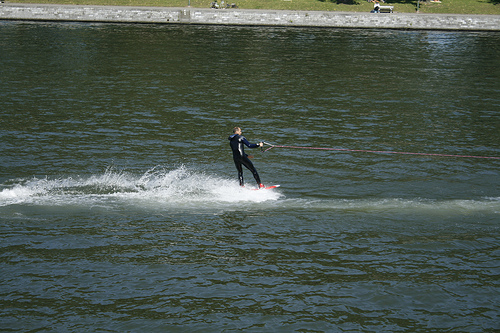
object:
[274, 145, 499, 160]
line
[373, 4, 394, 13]
bench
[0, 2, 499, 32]
shoreline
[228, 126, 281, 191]
ski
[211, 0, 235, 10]
people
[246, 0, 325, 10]
grass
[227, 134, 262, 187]
wet suit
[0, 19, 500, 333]
ripple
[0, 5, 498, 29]
wall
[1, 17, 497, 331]
water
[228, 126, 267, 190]
man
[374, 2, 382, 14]
person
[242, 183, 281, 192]
board